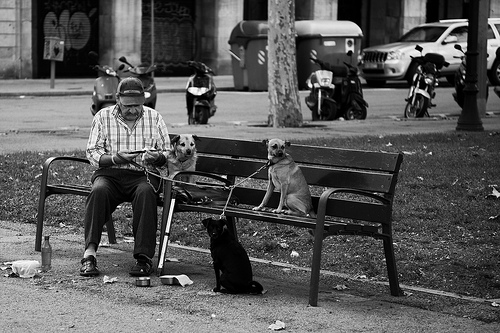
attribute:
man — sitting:
[81, 78, 172, 276]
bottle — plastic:
[40, 234, 51, 271]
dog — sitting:
[165, 134, 201, 186]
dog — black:
[201, 216, 264, 293]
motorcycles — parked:
[91, 44, 492, 124]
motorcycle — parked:
[176, 59, 218, 124]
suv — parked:
[358, 18, 499, 86]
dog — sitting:
[253, 139, 317, 218]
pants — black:
[84, 167, 162, 257]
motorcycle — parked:
[400, 45, 449, 118]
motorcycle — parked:
[305, 52, 338, 120]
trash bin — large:
[294, 20, 364, 91]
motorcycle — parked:
[319, 55, 370, 120]